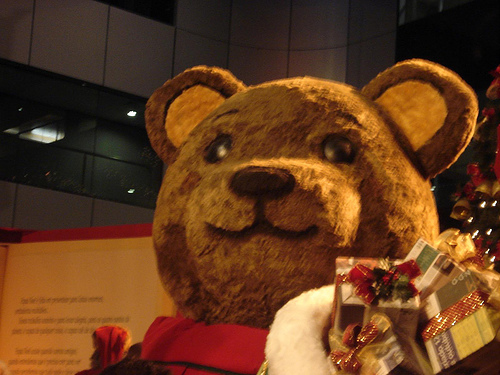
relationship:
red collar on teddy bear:
[146, 310, 261, 374] [127, 53, 457, 353]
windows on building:
[1, 66, 167, 216] [0, 0, 403, 230]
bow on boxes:
[327, 255, 428, 313] [289, 235, 499, 372]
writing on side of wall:
[8, 290, 134, 372] [0, 236, 180, 371]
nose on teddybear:
[227, 160, 298, 203] [89, 56, 479, 373]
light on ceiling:
[126, 110, 136, 117] [2, 60, 148, 132]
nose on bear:
[229, 165, 296, 199] [149, 51, 476, 350]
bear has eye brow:
[100, 58, 497, 375] [193, 105, 256, 130]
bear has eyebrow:
[77, 54, 491, 373] [333, 105, 365, 132]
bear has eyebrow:
[77, 54, 491, 373] [205, 105, 239, 124]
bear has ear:
[77, 54, 491, 373] [358, 53, 486, 185]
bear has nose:
[100, 58, 497, 375] [228, 166, 292, 200]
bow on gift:
[358, 258, 426, 309] [328, 247, 427, 343]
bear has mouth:
[77, 54, 491, 373] [201, 205, 321, 243]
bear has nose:
[77, 54, 491, 373] [227, 160, 298, 203]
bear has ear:
[77, 54, 491, 373] [142, 63, 244, 160]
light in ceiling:
[4, 112, 63, 147] [0, 62, 153, 143]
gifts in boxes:
[324, 248, 466, 363] [304, 221, 498, 373]